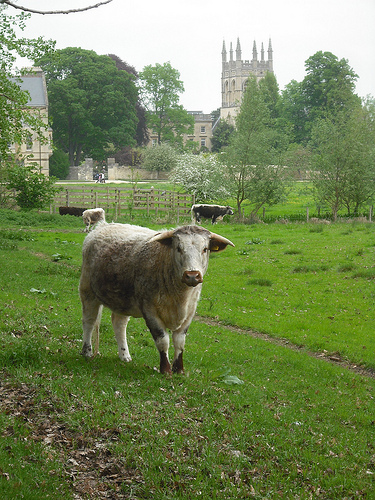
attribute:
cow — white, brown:
[67, 198, 234, 373]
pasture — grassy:
[1, 183, 373, 496]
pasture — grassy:
[63, 377, 357, 494]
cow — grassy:
[75, 218, 231, 374]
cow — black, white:
[184, 200, 241, 228]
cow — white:
[81, 215, 210, 373]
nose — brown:
[182, 260, 203, 288]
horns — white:
[148, 229, 235, 254]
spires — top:
[212, 35, 275, 69]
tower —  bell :
[223, 41, 274, 126]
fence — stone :
[74, 183, 180, 217]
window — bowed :
[40, 125, 54, 154]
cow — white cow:
[79, 165, 216, 359]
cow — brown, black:
[189, 200, 235, 225]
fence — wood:
[36, 178, 195, 217]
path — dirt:
[217, 315, 360, 369]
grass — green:
[229, 226, 372, 316]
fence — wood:
[238, 202, 366, 222]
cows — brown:
[54, 203, 85, 216]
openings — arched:
[221, 80, 239, 90]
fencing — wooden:
[2, 172, 213, 217]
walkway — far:
[49, 179, 143, 185]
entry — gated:
[91, 160, 110, 180]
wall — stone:
[62, 155, 171, 179]